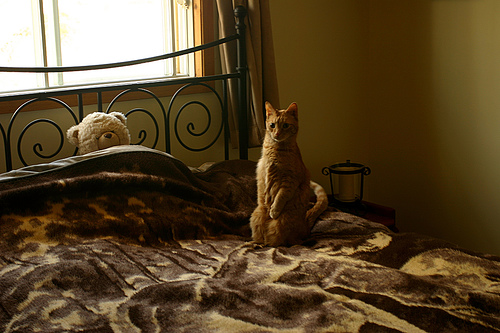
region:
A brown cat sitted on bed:
[256, 89, 325, 234]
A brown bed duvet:
[129, 261, 280, 314]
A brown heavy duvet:
[344, 241, 446, 329]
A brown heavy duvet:
[24, 171, 165, 251]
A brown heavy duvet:
[172, 164, 271, 221]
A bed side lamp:
[306, 156, 370, 198]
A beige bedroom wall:
[405, 125, 474, 207]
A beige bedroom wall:
[294, 16, 363, 122]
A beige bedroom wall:
[433, 24, 484, 144]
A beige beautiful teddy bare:
[70, 113, 145, 153]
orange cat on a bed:
[245, 95, 329, 253]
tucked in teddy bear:
[65, 100, 147, 202]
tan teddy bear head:
[57, 106, 142, 163]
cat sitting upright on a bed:
[245, 88, 330, 260]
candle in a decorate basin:
[320, 152, 376, 223]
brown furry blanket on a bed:
[142, 243, 277, 325]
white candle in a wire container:
[300, 138, 396, 220]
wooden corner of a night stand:
[325, 188, 406, 231]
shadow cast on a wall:
[320, 40, 477, 150]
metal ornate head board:
[114, 52, 244, 164]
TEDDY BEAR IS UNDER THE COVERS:
[72, 108, 140, 158]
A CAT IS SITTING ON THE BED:
[248, 102, 339, 252]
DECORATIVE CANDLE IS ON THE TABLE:
[327, 157, 373, 214]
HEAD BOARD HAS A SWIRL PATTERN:
[2, 6, 245, 170]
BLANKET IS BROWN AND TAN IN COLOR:
[9, 185, 307, 331]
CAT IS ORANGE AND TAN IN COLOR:
[256, 97, 323, 239]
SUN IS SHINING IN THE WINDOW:
[25, 7, 188, 69]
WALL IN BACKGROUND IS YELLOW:
[298, 24, 450, 164]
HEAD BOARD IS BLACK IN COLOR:
[19, 9, 245, 156]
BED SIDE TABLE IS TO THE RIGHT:
[311, 187, 417, 247]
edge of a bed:
[177, 114, 225, 193]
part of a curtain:
[255, 73, 264, 92]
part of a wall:
[392, 135, 432, 156]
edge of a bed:
[331, 155, 382, 300]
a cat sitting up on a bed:
[138, 95, 337, 329]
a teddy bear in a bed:
[62, 103, 234, 283]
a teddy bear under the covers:
[22, 108, 245, 235]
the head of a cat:
[258, 95, 301, 143]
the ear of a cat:
[286, 100, 301, 115]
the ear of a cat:
[262, 99, 275, 119]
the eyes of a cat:
[267, 118, 293, 130]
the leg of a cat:
[269, 187, 290, 220]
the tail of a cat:
[305, 175, 328, 219]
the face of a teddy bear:
[92, 122, 117, 146]